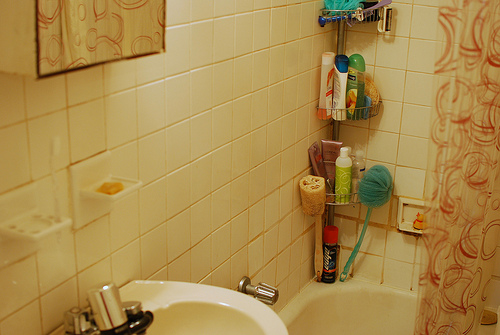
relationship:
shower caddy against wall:
[314, 3, 395, 280] [325, 3, 477, 284]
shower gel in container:
[345, 50, 367, 121] [298, 1, 396, 281]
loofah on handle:
[296, 176, 328, 281] [310, 219, 332, 277]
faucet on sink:
[73, 272, 144, 330] [183, 282, 259, 334]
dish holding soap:
[85, 171, 147, 211] [98, 178, 128, 191]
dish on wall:
[85, 171, 147, 211] [5, 2, 346, 332]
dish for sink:
[79, 173, 144, 201] [53, 274, 295, 331]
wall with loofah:
[5, 2, 346, 332] [292, 168, 332, 286]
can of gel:
[325, 224, 336, 280] [313, 217, 353, 280]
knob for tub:
[239, 266, 299, 308] [283, 270, 422, 332]